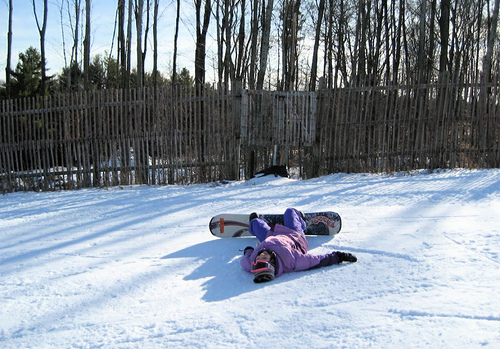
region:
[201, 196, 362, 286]
person has a snowboard on feet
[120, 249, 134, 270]
white snow on hill side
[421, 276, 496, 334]
white snow on hill side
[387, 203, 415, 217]
white snow on hill side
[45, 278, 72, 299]
white snow on hill side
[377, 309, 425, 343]
white snow on hill side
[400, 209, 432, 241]
white snow on hill side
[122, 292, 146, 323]
white snow on hill side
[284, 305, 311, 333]
white snow on hill side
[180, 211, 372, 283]
person lying in white snow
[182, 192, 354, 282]
woman lying in white snow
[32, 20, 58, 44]
white clouds in blue sky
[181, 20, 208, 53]
white clouds in blue sky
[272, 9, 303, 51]
white clouds in blue sky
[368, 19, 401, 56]
white clouds in blue sky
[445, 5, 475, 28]
white clouds in blue sky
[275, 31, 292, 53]
white clouds in blue sky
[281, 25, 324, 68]
white clouds in blue sky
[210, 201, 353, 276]
person in snow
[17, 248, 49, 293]
white snow on hill side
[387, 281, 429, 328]
white snow on hill side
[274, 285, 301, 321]
white snow on hill side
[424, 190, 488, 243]
white snow on hill side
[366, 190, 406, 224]
white snow on hill side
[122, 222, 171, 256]
white snow on hill side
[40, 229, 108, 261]
white snow on hill side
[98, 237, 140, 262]
white snow on hill side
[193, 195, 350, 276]
female lying in white snow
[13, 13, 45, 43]
white clouds in blue sky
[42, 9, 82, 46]
white clouds in blue sky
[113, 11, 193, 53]
white clouds in blue sky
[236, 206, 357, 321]
The girl on the ground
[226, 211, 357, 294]
A girl on the ground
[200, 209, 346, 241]
The snowboard the girl is wearing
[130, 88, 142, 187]
wooden stick on fence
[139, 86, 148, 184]
wooden stick on fence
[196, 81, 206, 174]
wooden stick on fence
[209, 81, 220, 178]
wooden stick on fence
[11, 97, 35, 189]
wooden stick on fence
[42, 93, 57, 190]
wooden stick on fence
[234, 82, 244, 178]
wooden stick on fence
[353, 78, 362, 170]
wooden stick on fence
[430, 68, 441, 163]
wooden stick on fence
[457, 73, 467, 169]
wooden stick on fence